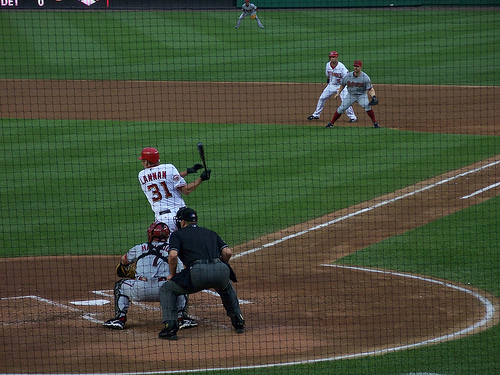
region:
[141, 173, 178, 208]
31 on the back of a jersey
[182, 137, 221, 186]
a player swinging a bat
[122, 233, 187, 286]
a player wearing a grey jersey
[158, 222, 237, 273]
an umpire wearing a black shirt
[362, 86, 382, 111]
a player wearing a baseball glove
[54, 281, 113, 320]
home plate on a baseball field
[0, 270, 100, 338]
batters box for right handed hitters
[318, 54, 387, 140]
a player ready to make a play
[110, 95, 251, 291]
the just hit the ball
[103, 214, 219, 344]
he is a baseball catcher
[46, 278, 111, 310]
this is home plate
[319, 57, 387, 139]
he is the first baseman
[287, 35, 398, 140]
he is preparing to run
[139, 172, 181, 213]
he wears number 31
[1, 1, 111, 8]
this is a digital scoreboard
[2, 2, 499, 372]
there is a large net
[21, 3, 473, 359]
Six men on a baseball field.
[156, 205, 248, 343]
The umpire is wearing a face mask.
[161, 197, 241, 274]
The empire is wearing a dark blue shirt.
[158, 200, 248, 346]
The umpire is wearing grey pants.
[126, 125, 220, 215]
The batter has the number 31 on his shirt.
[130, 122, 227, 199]
The batter is wearing black gloves.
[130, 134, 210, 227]
The batter is wearing a red and white uniform.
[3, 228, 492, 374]
The dirt around home plate.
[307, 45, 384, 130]
Two players in different team uniforms.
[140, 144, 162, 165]
red batting helmet on head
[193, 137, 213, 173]
black base ball bat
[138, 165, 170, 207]
numbers on back of shirt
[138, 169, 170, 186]
red letters on back of jersey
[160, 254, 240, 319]
grey pants of umpire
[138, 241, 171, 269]
black straps on shirt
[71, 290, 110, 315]
white home plate on dirt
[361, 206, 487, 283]
grass part of base ball field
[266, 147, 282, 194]
There is a patch of green grass here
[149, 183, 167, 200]
This man has a number 31 on his back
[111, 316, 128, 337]
This catcher has black shoes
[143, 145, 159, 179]
This man is wearing a red helmet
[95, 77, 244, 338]
Jackson Mingus took this photo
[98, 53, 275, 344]
This photo was taken in St. Louis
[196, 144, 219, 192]
This man has a black bat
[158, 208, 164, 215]
This man is wearing a wide belt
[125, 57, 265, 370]
This photo is really quite engaging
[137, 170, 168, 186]
batter's last name on team jersey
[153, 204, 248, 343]
umpire crouched behind hind catcher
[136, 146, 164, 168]
red helmet covering batter's head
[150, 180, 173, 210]
The number 31 on the jersey.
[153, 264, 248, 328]
The mans gray pants.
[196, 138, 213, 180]
The black baseball bat.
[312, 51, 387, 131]
The two baseball players.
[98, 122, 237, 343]
Three men playing baseball.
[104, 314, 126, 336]
The black and white sneaker.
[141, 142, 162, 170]
The red baseball helmet.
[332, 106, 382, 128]
The red baseball socks.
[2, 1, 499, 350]
men playing professional baseball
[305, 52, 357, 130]
runner is at first base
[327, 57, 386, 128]
first baseman is awaiting the play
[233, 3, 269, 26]
person is playing outfield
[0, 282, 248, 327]
white chalk outlines the batter boxes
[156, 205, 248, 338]
the umpire is ready to call plays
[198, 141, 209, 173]
bat is black